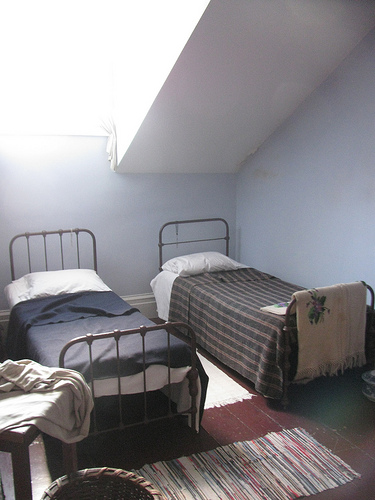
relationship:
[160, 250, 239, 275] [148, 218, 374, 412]
pillow on bed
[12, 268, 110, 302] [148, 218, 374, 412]
pillow on bed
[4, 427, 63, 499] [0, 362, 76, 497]
legs of desk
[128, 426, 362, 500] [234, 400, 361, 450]
carpet in floor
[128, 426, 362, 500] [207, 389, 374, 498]
carpet in floor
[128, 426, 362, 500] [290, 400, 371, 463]
carpet in ground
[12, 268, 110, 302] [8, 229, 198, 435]
pillow on bed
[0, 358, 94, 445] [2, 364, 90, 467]
blanket on table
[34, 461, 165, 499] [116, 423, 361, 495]
basket beside mat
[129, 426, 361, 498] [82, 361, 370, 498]
mat on floor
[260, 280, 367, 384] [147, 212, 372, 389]
blanket on bed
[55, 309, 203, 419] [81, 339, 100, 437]
footboard has iron rod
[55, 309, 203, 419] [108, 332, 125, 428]
footboard has iron rod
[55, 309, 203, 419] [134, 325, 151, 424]
footboard has iron rod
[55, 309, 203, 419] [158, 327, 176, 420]
footboard has iron rod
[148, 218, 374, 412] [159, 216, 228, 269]
bed has frame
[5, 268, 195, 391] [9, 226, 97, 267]
bed has frame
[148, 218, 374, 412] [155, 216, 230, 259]
bed has frame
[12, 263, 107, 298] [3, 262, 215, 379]
pillow on bed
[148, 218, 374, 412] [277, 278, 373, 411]
bed has end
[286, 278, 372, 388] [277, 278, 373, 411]
blanket on end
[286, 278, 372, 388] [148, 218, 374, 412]
blanket on bed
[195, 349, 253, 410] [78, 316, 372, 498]
rug on floor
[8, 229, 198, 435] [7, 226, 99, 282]
bed has top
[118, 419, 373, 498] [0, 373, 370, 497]
carpet on ground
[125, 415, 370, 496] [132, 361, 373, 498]
mat on floor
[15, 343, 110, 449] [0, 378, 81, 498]
blanket on table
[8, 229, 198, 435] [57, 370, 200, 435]
bed has frame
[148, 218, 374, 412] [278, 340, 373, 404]
bed has frame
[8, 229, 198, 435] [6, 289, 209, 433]
bed has blanket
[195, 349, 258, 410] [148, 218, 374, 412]
rug between bed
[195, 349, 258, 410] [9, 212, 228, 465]
rug between bed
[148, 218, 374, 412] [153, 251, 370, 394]
bed has blanket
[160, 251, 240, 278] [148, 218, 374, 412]
pillow lying on top of bed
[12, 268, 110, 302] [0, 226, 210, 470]
pillow lying on top of bed